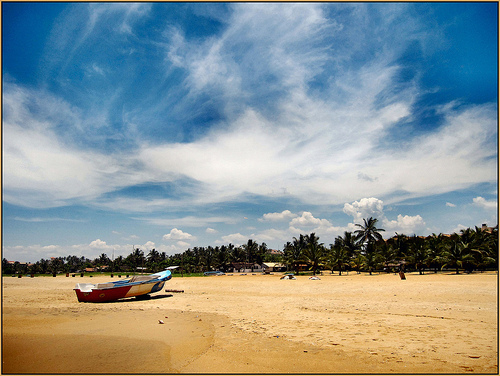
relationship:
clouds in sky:
[1, 1, 499, 208] [2, 2, 498, 263]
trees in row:
[1, 215, 499, 285] [0, 215, 498, 281]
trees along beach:
[1, 215, 499, 285] [1, 270, 497, 375]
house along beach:
[260, 257, 291, 271] [1, 270, 497, 375]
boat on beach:
[67, 266, 175, 305] [1, 270, 497, 375]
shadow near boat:
[111, 290, 176, 307] [67, 266, 175, 305]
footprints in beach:
[334, 330, 498, 373] [1, 270, 497, 375]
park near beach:
[1, 260, 210, 280] [1, 270, 497, 375]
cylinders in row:
[13, 270, 134, 280] [0, 215, 498, 281]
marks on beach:
[0, 304, 469, 375] [1, 270, 497, 375]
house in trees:
[260, 257, 291, 271] [1, 215, 499, 285]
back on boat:
[72, 273, 132, 306] [67, 266, 175, 305]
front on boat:
[151, 266, 176, 294] [67, 266, 175, 305]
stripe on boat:
[125, 280, 155, 300] [67, 266, 175, 305]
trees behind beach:
[1, 215, 499, 285] [1, 270, 497, 375]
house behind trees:
[260, 257, 291, 271] [1, 215, 499, 285]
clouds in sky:
[0, 192, 498, 261] [2, 2, 498, 263]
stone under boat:
[131, 290, 153, 303] [67, 266, 175, 305]